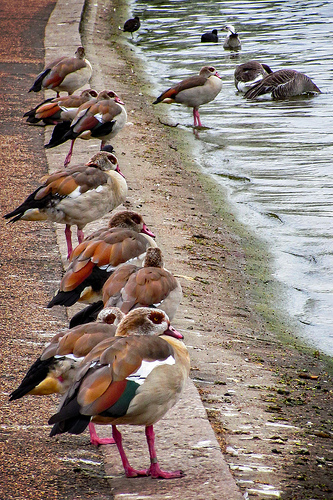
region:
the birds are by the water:
[48, 41, 214, 308]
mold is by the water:
[200, 234, 327, 356]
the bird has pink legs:
[95, 422, 192, 484]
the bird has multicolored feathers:
[68, 351, 134, 421]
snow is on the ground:
[192, 427, 284, 495]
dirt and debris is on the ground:
[269, 368, 311, 443]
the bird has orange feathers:
[75, 236, 115, 285]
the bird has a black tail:
[50, 408, 95, 454]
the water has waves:
[237, 187, 316, 268]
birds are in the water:
[189, 47, 326, 112]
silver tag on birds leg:
[140, 451, 168, 474]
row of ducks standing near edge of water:
[26, 39, 160, 483]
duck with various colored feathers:
[53, 307, 199, 482]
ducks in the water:
[150, 17, 319, 134]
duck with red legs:
[104, 410, 181, 481]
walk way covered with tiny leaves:
[4, 131, 47, 492]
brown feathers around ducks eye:
[135, 304, 171, 335]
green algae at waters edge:
[235, 228, 272, 333]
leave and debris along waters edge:
[266, 366, 327, 494]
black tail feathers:
[46, 392, 85, 448]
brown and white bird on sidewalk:
[21, 38, 96, 84]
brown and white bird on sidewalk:
[53, 300, 192, 472]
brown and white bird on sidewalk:
[84, 245, 185, 293]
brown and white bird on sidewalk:
[58, 213, 151, 268]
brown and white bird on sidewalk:
[8, 143, 132, 227]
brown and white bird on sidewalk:
[50, 82, 120, 139]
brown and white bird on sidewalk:
[155, 55, 217, 122]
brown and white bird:
[45, 302, 190, 481]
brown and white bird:
[5, 148, 132, 213]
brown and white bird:
[52, 80, 136, 133]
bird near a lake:
[64, 304, 179, 473]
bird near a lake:
[140, 244, 173, 305]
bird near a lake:
[101, 206, 143, 253]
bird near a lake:
[18, 142, 122, 218]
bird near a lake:
[55, 81, 119, 139]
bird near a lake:
[155, 52, 216, 132]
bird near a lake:
[122, 10, 148, 38]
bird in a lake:
[200, 18, 222, 46]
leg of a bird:
[135, 428, 187, 479]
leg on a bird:
[105, 423, 139, 481]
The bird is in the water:
[236, 59, 329, 105]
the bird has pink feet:
[86, 421, 176, 493]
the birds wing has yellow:
[83, 383, 175, 432]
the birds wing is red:
[70, 373, 143, 412]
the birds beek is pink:
[136, 318, 190, 362]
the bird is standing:
[153, 59, 265, 162]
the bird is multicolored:
[70, 331, 223, 457]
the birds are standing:
[7, 189, 199, 443]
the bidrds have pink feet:
[10, 389, 210, 487]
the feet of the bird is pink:
[72, 427, 189, 484]